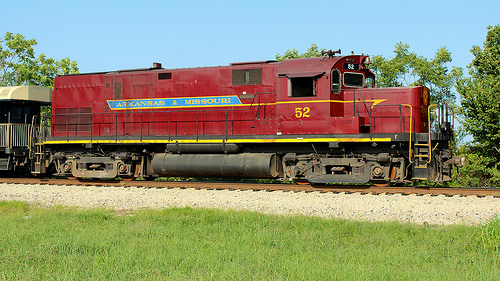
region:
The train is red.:
[35, 24, 452, 162]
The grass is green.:
[82, 223, 237, 279]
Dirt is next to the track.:
[53, 166, 395, 242]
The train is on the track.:
[35, 34, 446, 176]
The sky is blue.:
[60, 15, 218, 65]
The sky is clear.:
[3, 3, 494, 58]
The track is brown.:
[13, 145, 453, 207]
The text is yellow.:
[95, 85, 267, 107]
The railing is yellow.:
[391, 88, 439, 177]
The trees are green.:
[454, 30, 499, 155]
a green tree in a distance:
[2, 30, 37, 85]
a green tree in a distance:
[35, 55, 80, 106]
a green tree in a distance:
[272, 42, 333, 65]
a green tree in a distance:
[376, 36, 415, 104]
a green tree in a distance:
[409, 42, 463, 134]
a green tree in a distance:
[464, 31, 496, 174]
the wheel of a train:
[363, 150, 398, 185]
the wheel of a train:
[282, 153, 319, 189]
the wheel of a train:
[113, 157, 142, 182]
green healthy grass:
[0, 202, 498, 278]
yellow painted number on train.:
[288, 104, 314, 119]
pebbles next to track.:
[140, 196, 242, 206]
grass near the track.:
[172, 225, 279, 266]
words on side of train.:
[107, 95, 232, 112]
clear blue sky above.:
[124, 14, 195, 48]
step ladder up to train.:
[412, 142, 430, 174]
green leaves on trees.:
[467, 58, 492, 135]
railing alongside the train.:
[95, 112, 223, 131]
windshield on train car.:
[339, 75, 364, 85]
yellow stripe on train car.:
[237, 136, 331, 146]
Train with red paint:
[10, 17, 482, 222]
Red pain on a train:
[30, 50, 434, 160]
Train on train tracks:
[6, 50, 488, 226]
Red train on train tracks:
[23, 47, 493, 209]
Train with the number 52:
[52, 55, 441, 148]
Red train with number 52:
[42, 45, 449, 185]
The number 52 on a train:
[30, 57, 451, 171]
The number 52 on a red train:
[35, 66, 470, 168]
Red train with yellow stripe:
[10, 37, 470, 194]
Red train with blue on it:
[25, 47, 455, 181]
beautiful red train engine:
[0, 45, 471, 215]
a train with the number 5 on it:
[255, 80, 365, 156]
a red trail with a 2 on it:
[229, 69, 402, 192]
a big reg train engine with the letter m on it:
[36, 55, 446, 190]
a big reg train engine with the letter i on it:
[61, 62, 394, 167]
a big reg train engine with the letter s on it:
[90, 66, 277, 146]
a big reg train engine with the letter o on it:
[53, 56, 398, 187]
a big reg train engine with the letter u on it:
[63, 55, 423, 175]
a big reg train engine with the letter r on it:
[70, 58, 401, 184]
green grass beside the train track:
[16, 199, 444, 279]